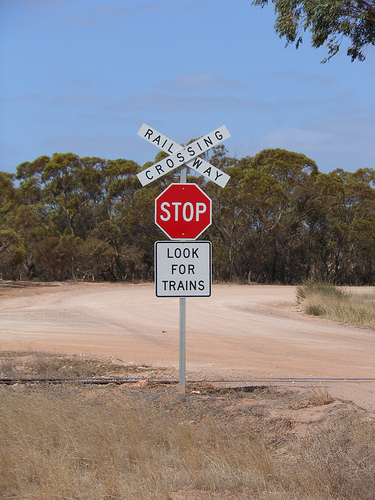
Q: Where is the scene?
A: It is rural.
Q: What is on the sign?
A: Look out for trains.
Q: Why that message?
A: It is a raiiway crossing.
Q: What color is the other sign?
A: Red.